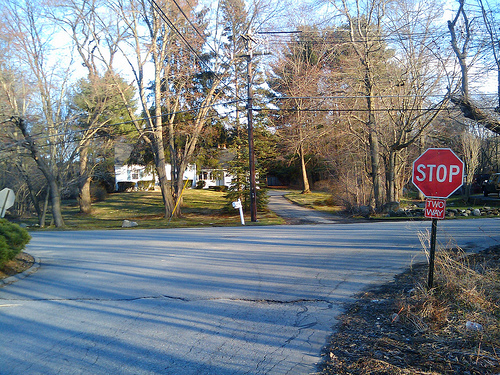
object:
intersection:
[0, 216, 500, 375]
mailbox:
[232, 198, 246, 225]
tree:
[400, 1, 499, 206]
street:
[13, 218, 500, 250]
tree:
[0, 2, 65, 229]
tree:
[271, 21, 338, 196]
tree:
[101, 0, 230, 213]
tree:
[381, 6, 455, 207]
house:
[112, 162, 260, 193]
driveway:
[258, 186, 383, 224]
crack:
[0, 295, 350, 312]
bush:
[1, 217, 34, 269]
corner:
[0, 246, 42, 287]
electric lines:
[0, 0, 500, 157]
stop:
[416, 164, 461, 183]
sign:
[424, 198, 446, 219]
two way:
[427, 201, 445, 216]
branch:
[445, 0, 500, 134]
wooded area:
[0, 137, 284, 227]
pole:
[246, 18, 257, 222]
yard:
[29, 187, 287, 230]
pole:
[428, 218, 438, 288]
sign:
[412, 148, 465, 199]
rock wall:
[354, 202, 500, 218]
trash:
[465, 321, 483, 332]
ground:
[315, 244, 500, 375]